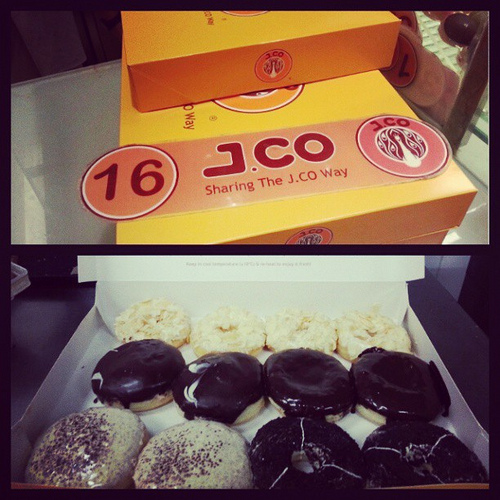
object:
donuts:
[22, 296, 488, 485]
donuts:
[90, 340, 488, 492]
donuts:
[113, 296, 412, 364]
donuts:
[25, 407, 250, 490]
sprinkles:
[30, 406, 121, 489]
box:
[77, 9, 477, 245]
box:
[0, 255, 500, 490]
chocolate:
[172, 352, 264, 426]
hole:
[209, 364, 224, 381]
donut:
[21, 406, 149, 491]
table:
[117, 56, 479, 246]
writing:
[187, 262, 314, 267]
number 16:
[94, 160, 164, 200]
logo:
[356, 114, 453, 177]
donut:
[91, 339, 185, 411]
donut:
[263, 347, 355, 421]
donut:
[350, 346, 451, 424]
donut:
[250, 416, 362, 489]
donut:
[364, 421, 487, 489]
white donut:
[134, 422, 252, 489]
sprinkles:
[137, 423, 222, 489]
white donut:
[118, 301, 190, 345]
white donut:
[191, 305, 266, 356]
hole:
[291, 448, 320, 474]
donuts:
[90, 343, 450, 426]